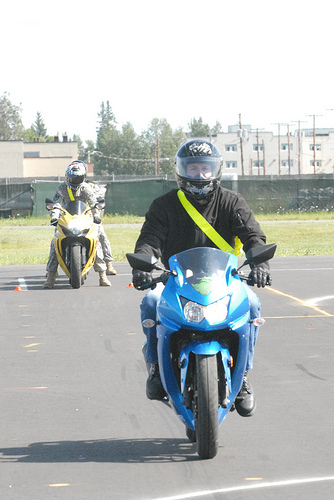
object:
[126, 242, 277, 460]
bike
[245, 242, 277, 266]
mirror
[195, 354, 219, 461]
wheel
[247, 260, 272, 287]
glove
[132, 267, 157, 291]
glove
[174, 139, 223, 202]
helmet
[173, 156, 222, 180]
visor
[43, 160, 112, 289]
man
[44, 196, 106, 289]
motor bike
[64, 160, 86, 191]
helmet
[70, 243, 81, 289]
tire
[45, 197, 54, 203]
mirror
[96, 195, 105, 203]
mirror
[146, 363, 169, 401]
boot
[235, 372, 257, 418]
boot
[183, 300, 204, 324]
headlight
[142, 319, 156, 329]
turn signal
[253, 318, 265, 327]
turn signal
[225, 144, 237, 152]
window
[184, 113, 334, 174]
building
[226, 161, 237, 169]
window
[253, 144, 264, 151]
window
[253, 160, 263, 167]
window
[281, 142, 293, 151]
window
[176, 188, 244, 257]
strap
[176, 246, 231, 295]
windshield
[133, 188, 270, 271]
jacket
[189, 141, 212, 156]
emblem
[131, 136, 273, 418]
man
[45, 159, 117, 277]
passenger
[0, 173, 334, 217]
fence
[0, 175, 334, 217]
tarp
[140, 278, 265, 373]
jeans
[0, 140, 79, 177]
building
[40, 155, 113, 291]
riders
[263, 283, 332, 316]
line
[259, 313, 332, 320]
line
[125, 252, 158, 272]
mirror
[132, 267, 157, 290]
hand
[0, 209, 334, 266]
grass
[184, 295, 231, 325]
headlights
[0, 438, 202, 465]
shadow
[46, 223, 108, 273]
pants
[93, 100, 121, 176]
tree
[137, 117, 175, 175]
tree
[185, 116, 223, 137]
tree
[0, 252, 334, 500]
pavement